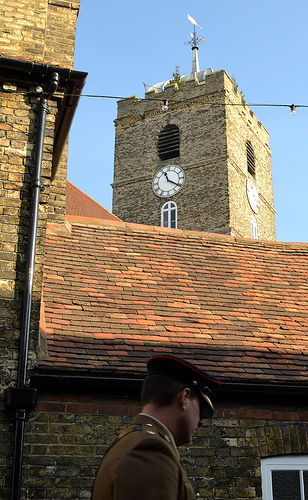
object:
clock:
[152, 164, 185, 198]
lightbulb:
[290, 110, 295, 116]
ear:
[179, 387, 191, 409]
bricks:
[0, 395, 307, 500]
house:
[0, 0, 308, 500]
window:
[260, 456, 308, 500]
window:
[251, 214, 259, 240]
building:
[109, 69, 274, 243]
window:
[154, 124, 179, 160]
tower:
[109, 13, 276, 243]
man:
[93, 346, 222, 498]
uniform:
[91, 412, 200, 500]